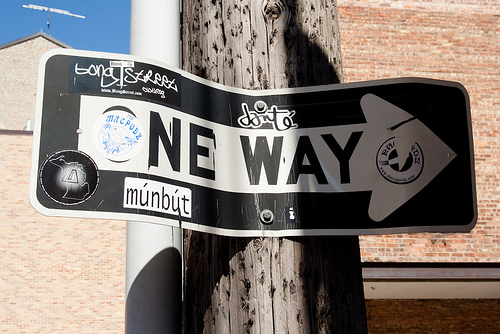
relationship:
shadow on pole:
[123, 245, 183, 330] [123, 0, 181, 331]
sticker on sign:
[44, 145, 101, 205] [32, 50, 481, 234]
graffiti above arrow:
[234, 97, 300, 134] [93, 131, 450, 184]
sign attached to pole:
[32, 50, 481, 234] [180, 0, 366, 332]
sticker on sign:
[44, 145, 101, 205] [53, 45, 477, 230]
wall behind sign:
[369, 9, 490, 147] [80, 66, 498, 237]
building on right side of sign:
[337, 9, 497, 331] [32, 50, 481, 234]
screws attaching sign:
[247, 94, 274, 118] [32, 50, 481, 234]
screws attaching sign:
[255, 204, 276, 224] [32, 50, 481, 234]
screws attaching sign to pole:
[247, 94, 274, 118] [180, 0, 366, 334]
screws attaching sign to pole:
[255, 204, 276, 224] [180, 0, 366, 334]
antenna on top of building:
[12, 0, 90, 32] [8, 24, 124, 331]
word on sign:
[225, 116, 376, 206] [32, 50, 481, 234]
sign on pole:
[32, 50, 481, 234] [180, 0, 366, 332]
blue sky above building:
[0, 1, 132, 53] [2, 0, 497, 329]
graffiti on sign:
[74, 58, 179, 99] [32, 50, 481, 234]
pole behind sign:
[180, 0, 366, 334] [58, 42, 499, 279]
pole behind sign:
[123, 0, 181, 331] [32, 50, 481, 234]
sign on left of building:
[32, 50, 481, 234] [8, 24, 124, 331]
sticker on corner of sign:
[44, 145, 101, 205] [32, 50, 481, 234]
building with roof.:
[8, 24, 124, 331] [10, 19, 104, 80]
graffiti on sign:
[68, 54, 180, 99] [32, 50, 481, 234]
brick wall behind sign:
[345, 0, 497, 79] [32, 50, 481, 234]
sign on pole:
[122, 80, 372, 213] [180, 0, 366, 332]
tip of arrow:
[357, 92, 462, 220] [68, 87, 465, 226]